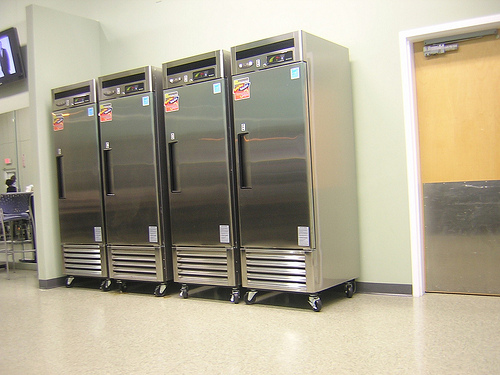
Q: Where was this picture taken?
A: A kitchen.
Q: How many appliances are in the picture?
A: Four.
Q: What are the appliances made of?
A: Metal.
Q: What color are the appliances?
A: Gray.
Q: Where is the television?
A: To the left of the appliances.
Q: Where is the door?
A: To the right of the appliances.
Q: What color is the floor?
A: Tan.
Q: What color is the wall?
A: White.